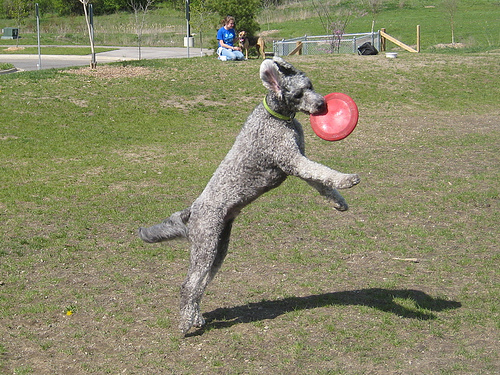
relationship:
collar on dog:
[257, 96, 297, 121] [140, 56, 360, 337]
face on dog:
[258, 55, 341, 129] [131, 26, 379, 361]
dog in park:
[238, 31, 267, 60] [1, 3, 499, 373]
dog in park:
[138, 57, 359, 339] [1, 3, 499, 373]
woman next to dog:
[216, 16, 244, 61] [140, 56, 360, 337]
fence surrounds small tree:
[265, 25, 390, 63] [321, 3, 352, 54]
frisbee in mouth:
[303, 89, 360, 141] [285, 69, 366, 148]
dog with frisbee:
[148, 59, 413, 361] [303, 89, 360, 141]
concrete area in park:
[7, 24, 306, 104] [23, 13, 433, 330]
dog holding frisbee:
[138, 57, 359, 339] [310, 92, 359, 141]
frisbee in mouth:
[310, 92, 359, 141] [300, 87, 326, 114]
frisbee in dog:
[310, 92, 359, 141] [140, 56, 360, 337]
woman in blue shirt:
[215, 18, 246, 63] [218, 26, 236, 46]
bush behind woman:
[202, 0, 264, 57] [217, 15, 246, 63]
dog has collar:
[138, 57, 359, 339] [238, 76, 341, 181]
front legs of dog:
[271, 112, 351, 203] [176, 24, 359, 305]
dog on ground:
[238, 32, 271, 58] [206, 59, 262, 71]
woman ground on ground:
[199, 12, 254, 67] [206, 59, 262, 71]